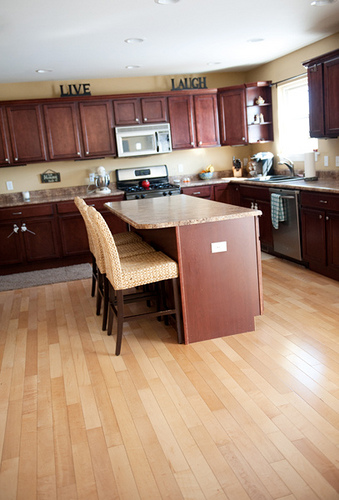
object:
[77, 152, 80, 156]
knob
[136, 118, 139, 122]
knob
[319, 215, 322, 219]
knob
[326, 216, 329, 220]
knob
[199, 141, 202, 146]
knob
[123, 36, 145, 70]
recessed lights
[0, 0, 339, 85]
ceiling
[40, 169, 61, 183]
sign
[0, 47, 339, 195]
wall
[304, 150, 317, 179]
towels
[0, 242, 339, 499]
ground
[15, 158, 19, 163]
knob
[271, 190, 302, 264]
dishwasher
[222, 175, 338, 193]
counter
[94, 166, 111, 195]
blender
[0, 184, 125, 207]
kitchen top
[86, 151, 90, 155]
knob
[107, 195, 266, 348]
island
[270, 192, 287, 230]
towel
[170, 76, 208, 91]
"laugh" sign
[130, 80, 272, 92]
cabinet top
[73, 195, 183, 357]
chairs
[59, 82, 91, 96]
art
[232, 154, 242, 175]
knives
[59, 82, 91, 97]
live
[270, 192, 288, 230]
cloth seat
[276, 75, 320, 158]
window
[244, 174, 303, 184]
sink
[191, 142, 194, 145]
knob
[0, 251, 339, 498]
floor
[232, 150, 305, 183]
stainless steel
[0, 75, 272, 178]
cabinets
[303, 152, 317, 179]
roll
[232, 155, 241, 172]
set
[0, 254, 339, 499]
surface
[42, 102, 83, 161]
door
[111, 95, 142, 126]
door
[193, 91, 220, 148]
door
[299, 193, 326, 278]
door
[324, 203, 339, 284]
door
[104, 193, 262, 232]
surface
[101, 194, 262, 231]
counter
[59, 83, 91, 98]
piece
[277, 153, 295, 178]
faucet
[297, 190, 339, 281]
cabinet